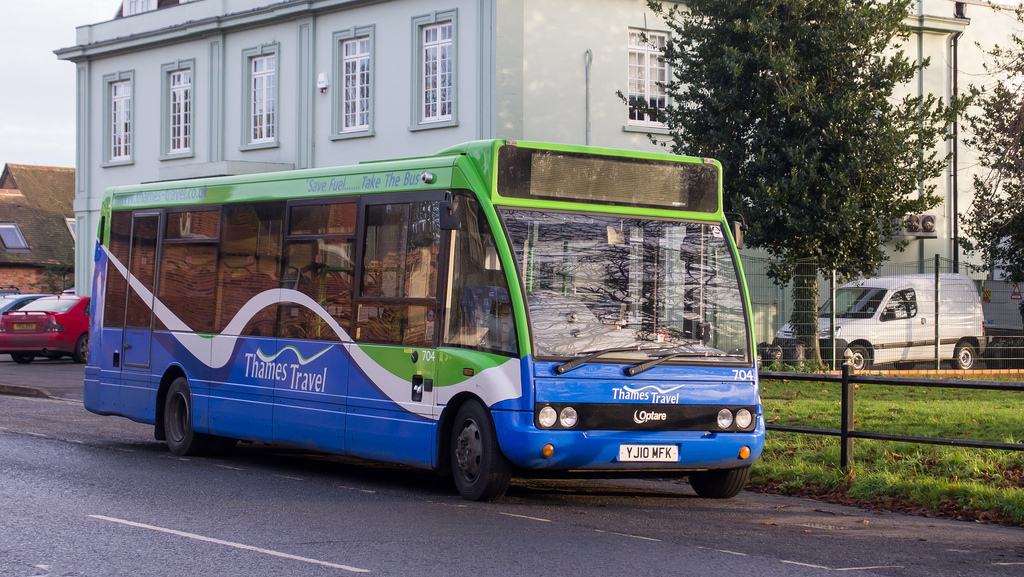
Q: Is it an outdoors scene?
A: Yes, it is outdoors.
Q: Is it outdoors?
A: Yes, it is outdoors.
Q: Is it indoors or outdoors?
A: It is outdoors.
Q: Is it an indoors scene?
A: No, it is outdoors.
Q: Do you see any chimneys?
A: No, there are no chimneys.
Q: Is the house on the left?
A: Yes, the house is on the left of the image.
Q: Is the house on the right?
A: No, the house is on the left of the image.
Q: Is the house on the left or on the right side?
A: The house is on the left of the image.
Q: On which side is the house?
A: The house is on the left of the image.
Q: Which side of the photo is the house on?
A: The house is on the left of the image.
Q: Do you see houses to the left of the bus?
A: Yes, there is a house to the left of the bus.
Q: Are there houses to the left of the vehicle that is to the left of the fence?
A: Yes, there is a house to the left of the bus.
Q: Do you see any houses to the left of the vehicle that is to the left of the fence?
A: Yes, there is a house to the left of the bus.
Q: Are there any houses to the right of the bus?
A: No, the house is to the left of the bus.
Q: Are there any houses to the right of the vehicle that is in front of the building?
A: No, the house is to the left of the bus.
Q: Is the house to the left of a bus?
A: Yes, the house is to the left of a bus.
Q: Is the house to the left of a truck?
A: No, the house is to the left of a bus.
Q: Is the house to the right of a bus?
A: No, the house is to the left of a bus.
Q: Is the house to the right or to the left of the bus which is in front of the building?
A: The house is to the left of the bus.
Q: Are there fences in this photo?
A: Yes, there is a fence.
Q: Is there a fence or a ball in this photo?
A: Yes, there is a fence.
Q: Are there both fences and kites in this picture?
A: No, there is a fence but no kites.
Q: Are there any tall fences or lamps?
A: Yes, there is a tall fence.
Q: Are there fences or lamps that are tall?
A: Yes, the fence is tall.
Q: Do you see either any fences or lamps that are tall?
A: Yes, the fence is tall.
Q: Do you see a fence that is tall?
A: Yes, there is a tall fence.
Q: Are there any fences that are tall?
A: Yes, there is a fence that is tall.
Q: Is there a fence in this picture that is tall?
A: Yes, there is a fence that is tall.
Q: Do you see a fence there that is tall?
A: Yes, there is a fence that is tall.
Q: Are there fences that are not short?
A: Yes, there is a tall fence.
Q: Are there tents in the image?
A: No, there are no tents.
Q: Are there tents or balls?
A: No, there are no tents or balls.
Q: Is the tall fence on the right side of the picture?
A: Yes, the fence is on the right of the image.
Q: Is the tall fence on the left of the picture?
A: No, the fence is on the right of the image.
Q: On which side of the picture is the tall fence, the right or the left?
A: The fence is on the right of the image.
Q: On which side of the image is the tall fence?
A: The fence is on the right of the image.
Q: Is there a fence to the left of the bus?
A: No, the fence is to the right of the bus.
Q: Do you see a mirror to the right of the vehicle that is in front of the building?
A: No, there is a fence to the right of the bus.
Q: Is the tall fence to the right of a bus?
A: Yes, the fence is to the right of a bus.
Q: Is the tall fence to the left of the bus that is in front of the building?
A: No, the fence is to the right of the bus.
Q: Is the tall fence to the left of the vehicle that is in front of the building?
A: No, the fence is to the right of the bus.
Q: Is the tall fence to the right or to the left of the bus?
A: The fence is to the right of the bus.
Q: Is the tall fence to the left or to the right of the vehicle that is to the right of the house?
A: The fence is to the right of the bus.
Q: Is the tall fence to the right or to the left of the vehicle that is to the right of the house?
A: The fence is to the right of the bus.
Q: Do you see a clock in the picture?
A: No, there are no clocks.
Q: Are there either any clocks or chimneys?
A: No, there are no clocks or chimneys.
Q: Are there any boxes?
A: No, there are no boxes.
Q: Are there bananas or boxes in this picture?
A: No, there are no boxes or bananas.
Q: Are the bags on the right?
A: Yes, the bags are on the right of the image.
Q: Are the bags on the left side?
A: No, the bags are on the right of the image.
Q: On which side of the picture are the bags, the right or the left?
A: The bags are on the right of the image.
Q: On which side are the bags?
A: The bags are on the right of the image.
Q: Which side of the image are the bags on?
A: The bags are on the right of the image.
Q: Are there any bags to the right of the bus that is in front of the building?
A: Yes, there are bags to the right of the bus.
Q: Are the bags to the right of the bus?
A: Yes, the bags are to the right of the bus.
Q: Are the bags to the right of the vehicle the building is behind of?
A: Yes, the bags are to the right of the bus.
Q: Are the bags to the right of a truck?
A: No, the bags are to the right of the bus.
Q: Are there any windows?
A: Yes, there is a window.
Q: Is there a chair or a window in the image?
A: Yes, there is a window.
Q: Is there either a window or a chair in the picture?
A: Yes, there is a window.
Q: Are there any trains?
A: No, there are no trains.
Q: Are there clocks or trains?
A: No, there are no trains or clocks.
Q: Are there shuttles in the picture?
A: No, there are no shuttles.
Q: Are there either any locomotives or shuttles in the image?
A: No, there are no shuttles or locomotives.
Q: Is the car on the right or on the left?
A: The car is on the right of the image.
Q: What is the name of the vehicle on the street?
A: The vehicle is a car.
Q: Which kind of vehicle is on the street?
A: The vehicle is a car.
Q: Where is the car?
A: The car is on the street.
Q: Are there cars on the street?
A: Yes, there is a car on the street.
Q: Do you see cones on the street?
A: No, there is a car on the street.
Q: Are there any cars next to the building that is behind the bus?
A: Yes, there is a car next to the building.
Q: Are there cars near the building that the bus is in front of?
A: Yes, there is a car near the building.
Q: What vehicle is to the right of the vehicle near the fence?
A: The vehicle is a car.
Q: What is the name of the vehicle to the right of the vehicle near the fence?
A: The vehicle is a car.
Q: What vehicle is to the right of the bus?
A: The vehicle is a car.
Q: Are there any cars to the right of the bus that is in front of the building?
A: Yes, there is a car to the right of the bus.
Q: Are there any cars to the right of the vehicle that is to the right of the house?
A: Yes, there is a car to the right of the bus.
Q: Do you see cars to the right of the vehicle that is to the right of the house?
A: Yes, there is a car to the right of the bus.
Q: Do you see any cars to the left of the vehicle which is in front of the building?
A: No, the car is to the right of the bus.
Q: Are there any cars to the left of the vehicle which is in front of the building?
A: No, the car is to the right of the bus.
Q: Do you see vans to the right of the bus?
A: No, there is a car to the right of the bus.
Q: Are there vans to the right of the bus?
A: No, there is a car to the right of the bus.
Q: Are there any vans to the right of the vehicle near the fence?
A: No, there is a car to the right of the bus.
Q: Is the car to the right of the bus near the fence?
A: Yes, the car is to the right of the bus.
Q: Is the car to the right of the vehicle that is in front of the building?
A: Yes, the car is to the right of the bus.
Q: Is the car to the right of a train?
A: No, the car is to the right of the bus.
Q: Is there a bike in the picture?
A: No, there are no bikes.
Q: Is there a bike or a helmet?
A: No, there are no bikes or helmets.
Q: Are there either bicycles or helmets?
A: No, there are no bicycles or helmets.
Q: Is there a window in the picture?
A: Yes, there is a window.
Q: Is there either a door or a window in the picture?
A: Yes, there is a window.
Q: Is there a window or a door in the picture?
A: Yes, there is a window.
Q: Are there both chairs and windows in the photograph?
A: No, there is a window but no chairs.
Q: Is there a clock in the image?
A: No, there are no clocks.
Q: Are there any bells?
A: No, there are no bells.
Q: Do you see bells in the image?
A: No, there are no bells.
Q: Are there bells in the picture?
A: No, there are no bells.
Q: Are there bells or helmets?
A: No, there are no bells or helmets.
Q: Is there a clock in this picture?
A: No, there are no clocks.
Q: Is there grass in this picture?
A: Yes, there is grass.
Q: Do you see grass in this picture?
A: Yes, there is grass.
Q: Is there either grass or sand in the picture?
A: Yes, there is grass.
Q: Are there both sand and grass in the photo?
A: No, there is grass but no sand.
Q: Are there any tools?
A: No, there are no tools.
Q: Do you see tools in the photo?
A: No, there are no tools.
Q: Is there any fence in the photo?
A: Yes, there is a fence.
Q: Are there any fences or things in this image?
A: Yes, there is a fence.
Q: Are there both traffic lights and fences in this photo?
A: No, there is a fence but no traffic lights.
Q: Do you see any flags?
A: No, there are no flags.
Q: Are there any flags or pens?
A: No, there are no flags or pens.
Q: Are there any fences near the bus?
A: Yes, there is a fence near the bus.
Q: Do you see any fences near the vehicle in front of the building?
A: Yes, there is a fence near the bus.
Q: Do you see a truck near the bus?
A: No, there is a fence near the bus.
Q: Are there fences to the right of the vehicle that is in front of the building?
A: Yes, there is a fence to the right of the bus.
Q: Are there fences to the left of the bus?
A: No, the fence is to the right of the bus.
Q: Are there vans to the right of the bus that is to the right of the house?
A: No, there is a fence to the right of the bus.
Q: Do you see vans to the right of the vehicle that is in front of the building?
A: No, there is a fence to the right of the bus.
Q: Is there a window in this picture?
A: Yes, there are windows.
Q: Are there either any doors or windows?
A: Yes, there are windows.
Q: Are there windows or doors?
A: Yes, there are windows.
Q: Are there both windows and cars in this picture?
A: Yes, there are both windows and a car.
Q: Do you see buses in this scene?
A: Yes, there is a bus.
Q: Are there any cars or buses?
A: Yes, there is a bus.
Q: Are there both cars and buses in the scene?
A: Yes, there are both a bus and a car.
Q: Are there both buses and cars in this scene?
A: Yes, there are both a bus and a car.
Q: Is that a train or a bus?
A: That is a bus.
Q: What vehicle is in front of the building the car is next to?
A: The vehicle is a bus.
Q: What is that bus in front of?
A: The bus is in front of the building.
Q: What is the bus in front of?
A: The bus is in front of the building.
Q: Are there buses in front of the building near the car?
A: Yes, there is a bus in front of the building.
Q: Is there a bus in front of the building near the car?
A: Yes, there is a bus in front of the building.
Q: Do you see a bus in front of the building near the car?
A: Yes, there is a bus in front of the building.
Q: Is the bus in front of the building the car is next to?
A: Yes, the bus is in front of the building.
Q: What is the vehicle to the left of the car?
A: The vehicle is a bus.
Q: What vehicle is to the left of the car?
A: The vehicle is a bus.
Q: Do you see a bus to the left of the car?
A: Yes, there is a bus to the left of the car.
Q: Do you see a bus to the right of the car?
A: No, the bus is to the left of the car.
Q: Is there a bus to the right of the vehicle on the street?
A: No, the bus is to the left of the car.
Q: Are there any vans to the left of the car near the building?
A: No, there is a bus to the left of the car.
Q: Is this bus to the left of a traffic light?
A: No, the bus is to the left of the car.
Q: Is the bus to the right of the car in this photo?
A: No, the bus is to the left of the car.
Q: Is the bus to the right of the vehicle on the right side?
A: No, the bus is to the left of the car.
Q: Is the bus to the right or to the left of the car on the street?
A: The bus is to the left of the car.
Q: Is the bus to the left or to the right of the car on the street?
A: The bus is to the left of the car.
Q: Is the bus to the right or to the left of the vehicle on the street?
A: The bus is to the left of the car.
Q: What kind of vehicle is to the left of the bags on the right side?
A: The vehicle is a bus.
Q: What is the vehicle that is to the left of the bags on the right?
A: The vehicle is a bus.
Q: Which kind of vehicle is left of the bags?
A: The vehicle is a bus.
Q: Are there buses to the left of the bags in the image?
A: Yes, there is a bus to the left of the bags.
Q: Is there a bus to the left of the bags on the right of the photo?
A: Yes, there is a bus to the left of the bags.